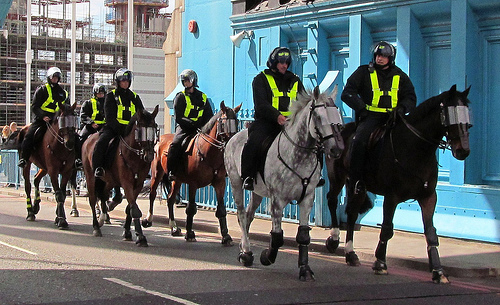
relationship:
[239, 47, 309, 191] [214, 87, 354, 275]
man riding a horse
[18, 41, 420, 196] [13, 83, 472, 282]
street patrol riding horseback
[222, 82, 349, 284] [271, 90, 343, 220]
horse wearing a harness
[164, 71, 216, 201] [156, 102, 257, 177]
man riding horse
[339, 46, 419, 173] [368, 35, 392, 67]
policeman in helmet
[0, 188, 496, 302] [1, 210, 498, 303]
road casting shadow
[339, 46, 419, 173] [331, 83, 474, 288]
policeman on horse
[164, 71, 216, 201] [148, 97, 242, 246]
man on horse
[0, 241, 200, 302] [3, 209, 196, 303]
lane separator on street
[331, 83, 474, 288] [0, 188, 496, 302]
horse on road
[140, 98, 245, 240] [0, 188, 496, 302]
horse on road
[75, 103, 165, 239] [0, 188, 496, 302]
horse on road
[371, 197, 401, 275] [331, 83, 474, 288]
leg of horse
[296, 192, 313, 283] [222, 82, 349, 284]
leg of horse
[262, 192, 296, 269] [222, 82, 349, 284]
leg of horse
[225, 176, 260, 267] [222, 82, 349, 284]
leg of horse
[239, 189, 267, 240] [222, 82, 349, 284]
leg of horse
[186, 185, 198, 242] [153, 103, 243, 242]
leg of horse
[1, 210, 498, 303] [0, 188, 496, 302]
shadow on road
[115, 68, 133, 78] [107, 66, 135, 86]
shield pushed up on helmet